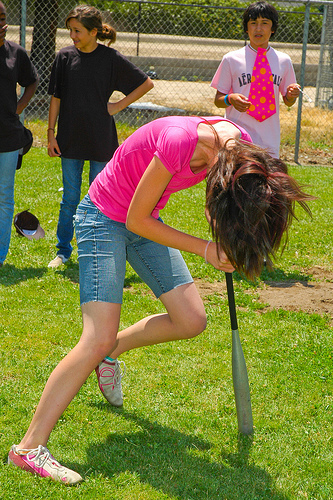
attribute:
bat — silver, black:
[226, 266, 255, 434]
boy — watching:
[211, 1, 303, 165]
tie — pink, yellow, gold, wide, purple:
[245, 48, 278, 122]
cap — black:
[14, 209, 48, 243]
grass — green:
[3, 120, 330, 499]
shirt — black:
[48, 42, 149, 165]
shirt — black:
[0, 39, 36, 155]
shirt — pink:
[89, 114, 253, 226]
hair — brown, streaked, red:
[200, 134, 314, 281]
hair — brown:
[64, 5, 117, 47]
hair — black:
[243, 1, 279, 40]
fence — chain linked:
[0, 1, 331, 170]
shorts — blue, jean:
[74, 192, 196, 302]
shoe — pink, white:
[5, 440, 85, 487]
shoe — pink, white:
[94, 352, 124, 411]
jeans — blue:
[54, 151, 110, 262]